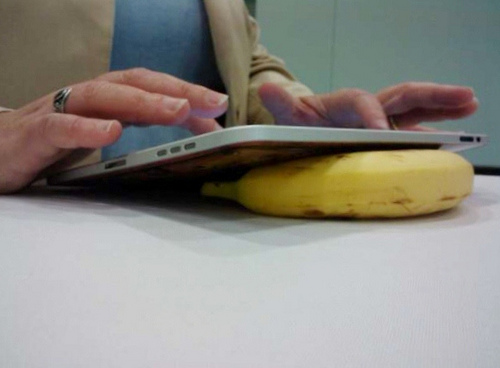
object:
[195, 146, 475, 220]
banana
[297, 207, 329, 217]
spot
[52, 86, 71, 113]
ring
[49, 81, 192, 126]
finger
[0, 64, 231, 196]
hand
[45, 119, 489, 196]
tablet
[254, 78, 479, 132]
hand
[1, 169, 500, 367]
table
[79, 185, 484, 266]
shadow of tablet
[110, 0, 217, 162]
shirt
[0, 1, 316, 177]
jacket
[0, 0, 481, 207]
person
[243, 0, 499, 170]
wall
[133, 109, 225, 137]
finger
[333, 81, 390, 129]
finger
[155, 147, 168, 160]
button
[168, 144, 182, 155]
button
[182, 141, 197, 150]
button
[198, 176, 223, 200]
tip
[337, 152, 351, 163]
spot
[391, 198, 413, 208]
spot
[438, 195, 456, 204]
spot